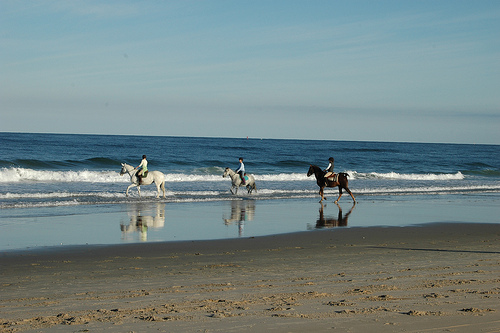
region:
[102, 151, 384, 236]
three people riding horses on the beach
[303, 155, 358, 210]
a person riding a brown horse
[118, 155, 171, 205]
a person riding a white horse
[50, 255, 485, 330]
wet sand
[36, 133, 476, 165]
a blue ocean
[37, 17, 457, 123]
a slightly hazy sky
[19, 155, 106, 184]
ocean waves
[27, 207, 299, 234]
the shoreline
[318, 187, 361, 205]
a horse's legs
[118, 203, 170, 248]
the reflection of a horse and rider on the shore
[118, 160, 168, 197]
White horse running in the water of a beach.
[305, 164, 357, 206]
Dark brown horse running on the beach.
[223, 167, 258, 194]
Horse with a rider running on the beach in the middle of two other horses.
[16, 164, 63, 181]
White waves coming out of the ocean.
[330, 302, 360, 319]
Piles of sand on the beach.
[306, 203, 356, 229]
Reflection of a brown horse on the wet sand of the beach.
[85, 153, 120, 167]
small sized wave in the water of the ocean.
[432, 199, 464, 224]
Wet sand on the beach.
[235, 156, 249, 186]
Man riding a horse that is in the middle of two other horses on the beach.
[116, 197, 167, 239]
Reflection of a white horse running on the beach.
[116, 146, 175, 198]
This is white horse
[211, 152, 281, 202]
This is grey horse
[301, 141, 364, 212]
This is black horse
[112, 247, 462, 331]
This is sand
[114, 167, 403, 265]
The water has reflection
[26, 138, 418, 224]
This water has waves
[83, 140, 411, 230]
These people look happy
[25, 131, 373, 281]
The water is blue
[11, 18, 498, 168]
The sky is blue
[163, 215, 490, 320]
This sand has been used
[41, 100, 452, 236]
three horses being ridden across the beach sand.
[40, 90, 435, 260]
horses being ridden across the beach sand.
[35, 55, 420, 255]
some horses being ridden across the beach sand.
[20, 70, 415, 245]
horses being ridden on the beach.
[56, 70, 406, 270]
three horses being ridden on the beach.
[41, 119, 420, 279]
people riding horses on the beach.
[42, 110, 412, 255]
three people riding horses on the beach.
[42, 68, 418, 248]
some people riding horses on the beach.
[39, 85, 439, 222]
people riding horses on the beach during daytime.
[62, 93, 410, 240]
people riding some beautiful horses on the beach.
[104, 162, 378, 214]
Three horses walking on a beach.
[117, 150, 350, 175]
Three people riding horses.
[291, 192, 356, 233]
The shadow of a brown horse reflected in the water.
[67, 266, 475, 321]
Foot prints of animals and people.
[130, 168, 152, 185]
A brown saddle.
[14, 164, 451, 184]
A white wave coming into the shore.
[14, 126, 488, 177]
An expanse of ocean.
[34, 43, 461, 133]
The light blue sky.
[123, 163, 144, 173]
The rider is holding the horse's reins.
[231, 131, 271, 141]
A ship or buoy bare perceptible in the distance.